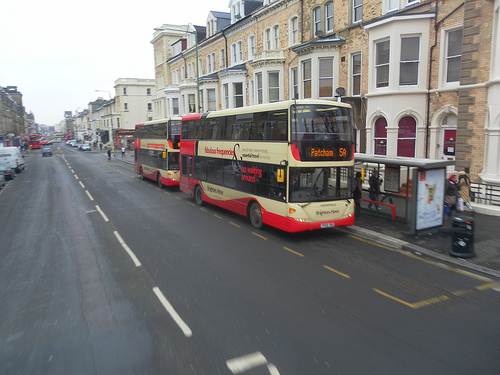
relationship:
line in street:
[149, 281, 197, 341] [19, 144, 436, 374]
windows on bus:
[273, 121, 286, 135] [182, 100, 357, 230]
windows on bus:
[231, 115, 253, 135] [182, 100, 357, 230]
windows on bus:
[202, 122, 224, 134] [182, 100, 357, 230]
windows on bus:
[182, 122, 190, 136] [182, 100, 357, 230]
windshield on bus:
[289, 163, 356, 201] [174, 97, 359, 238]